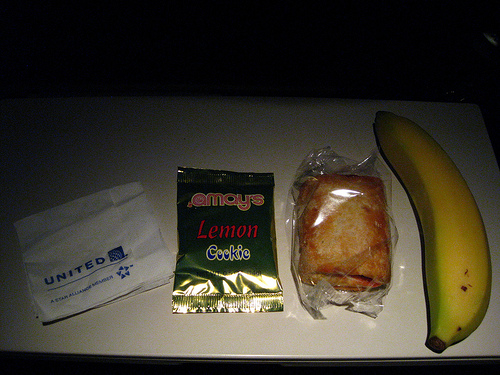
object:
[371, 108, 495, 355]
banana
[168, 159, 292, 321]
cookie package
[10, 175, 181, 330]
napkin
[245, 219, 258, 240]
letters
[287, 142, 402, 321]
plastic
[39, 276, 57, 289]
letters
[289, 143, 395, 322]
dessert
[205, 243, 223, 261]
letters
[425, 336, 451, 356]
stem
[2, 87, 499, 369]
table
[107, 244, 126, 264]
logo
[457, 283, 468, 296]
spot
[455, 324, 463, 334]
spot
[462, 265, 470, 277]
spot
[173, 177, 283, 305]
food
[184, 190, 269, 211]
brand name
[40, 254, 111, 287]
airline name